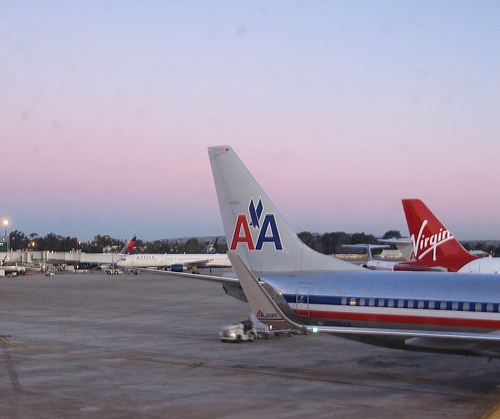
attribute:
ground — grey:
[1, 271, 498, 418]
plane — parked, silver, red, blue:
[126, 146, 498, 372]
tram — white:
[218, 311, 261, 346]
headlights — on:
[216, 330, 238, 339]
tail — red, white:
[401, 197, 471, 273]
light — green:
[309, 327, 321, 334]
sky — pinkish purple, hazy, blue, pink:
[1, 0, 499, 242]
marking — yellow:
[1, 331, 28, 352]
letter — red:
[225, 212, 257, 251]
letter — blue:
[254, 213, 284, 252]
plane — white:
[115, 235, 221, 268]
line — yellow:
[2, 334, 24, 349]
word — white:
[405, 220, 457, 264]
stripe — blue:
[284, 292, 499, 315]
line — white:
[289, 300, 500, 324]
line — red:
[290, 308, 499, 330]